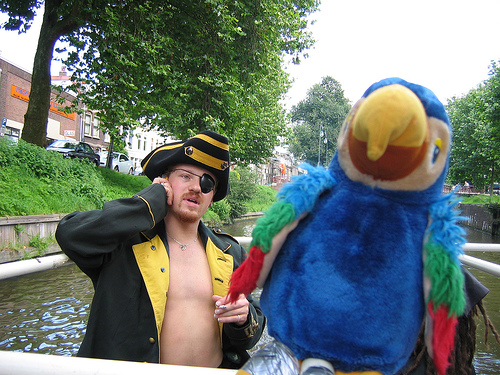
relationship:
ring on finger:
[166, 175, 170, 187] [154, 178, 172, 187]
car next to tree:
[42, 136, 100, 166] [0, 0, 312, 147]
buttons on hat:
[170, 138, 245, 175] [140, 127, 236, 204]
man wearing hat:
[48, 130, 271, 370] [120, 128, 250, 208]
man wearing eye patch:
[56, 133, 266, 370] [200, 173, 212, 193]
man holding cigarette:
[48, 130, 271, 370] [209, 295, 234, 313]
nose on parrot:
[350, 82, 425, 156] [225, 77, 490, 372]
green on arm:
[253, 218, 278, 244] [424, 242, 471, 316]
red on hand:
[222, 251, 264, 305] [208, 289, 250, 324]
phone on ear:
[159, 170, 169, 192] [159, 170, 173, 191]